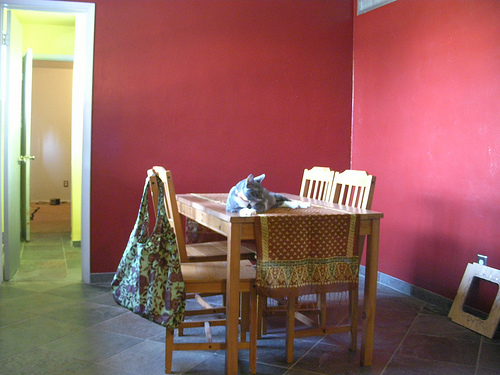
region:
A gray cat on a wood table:
[234, 168, 313, 220]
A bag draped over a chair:
[129, 170, 181, 333]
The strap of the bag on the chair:
[141, 169, 175, 234]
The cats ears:
[244, 173, 266, 187]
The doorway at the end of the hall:
[17, 47, 74, 272]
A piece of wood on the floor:
[441, 247, 495, 342]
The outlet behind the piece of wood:
[472, 254, 482, 269]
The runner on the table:
[202, 185, 349, 295]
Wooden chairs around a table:
[149, 166, 253, 369]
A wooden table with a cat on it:
[179, 178, 380, 368]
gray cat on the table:
[219, 165, 311, 220]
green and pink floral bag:
[107, 172, 193, 338]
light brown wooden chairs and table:
[142, 150, 387, 373]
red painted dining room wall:
[87, 0, 348, 282]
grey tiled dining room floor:
[2, 276, 499, 373]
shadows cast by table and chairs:
[201, 205, 498, 373]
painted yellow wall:
[5, 11, 85, 250]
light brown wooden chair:
[139, 165, 265, 373]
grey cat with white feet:
[218, 169, 310, 226]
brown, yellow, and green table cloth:
[247, 195, 363, 320]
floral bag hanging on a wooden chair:
[106, 165, 256, 370]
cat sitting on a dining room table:
[170, 170, 380, 365]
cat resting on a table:
[170, 170, 380, 370]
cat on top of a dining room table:
[171, 170, 381, 370]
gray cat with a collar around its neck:
[223, 170, 312, 214]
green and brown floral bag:
[108, 171, 187, 327]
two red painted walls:
[90, 1, 499, 328]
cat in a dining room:
[0, 2, 499, 374]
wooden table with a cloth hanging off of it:
[173, 190, 385, 373]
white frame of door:
[1, 0, 96, 286]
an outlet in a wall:
[476, 251, 487, 272]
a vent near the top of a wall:
[355, 0, 396, 16]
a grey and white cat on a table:
[226, 170, 316, 215]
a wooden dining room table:
[172, 184, 381, 374]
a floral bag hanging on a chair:
[105, 169, 193, 333]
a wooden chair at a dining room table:
[139, 165, 265, 373]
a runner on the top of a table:
[177, 184, 363, 317]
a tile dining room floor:
[2, 275, 497, 373]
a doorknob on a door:
[28, 150, 41, 165]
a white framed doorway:
[0, 1, 102, 285]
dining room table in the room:
[130, 139, 385, 361]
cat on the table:
[225, 170, 296, 218]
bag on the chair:
[101, 174, 192, 324]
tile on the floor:
[58, 332, 124, 366]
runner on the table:
[263, 221, 351, 294]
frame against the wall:
[446, 259, 496, 339]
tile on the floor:
[389, 330, 457, 359]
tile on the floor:
[69, 296, 114, 325]